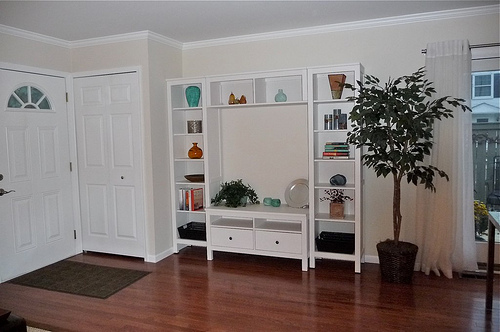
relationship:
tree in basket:
[335, 67, 473, 238] [377, 238, 419, 283]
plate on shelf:
[286, 178, 312, 209] [211, 202, 309, 216]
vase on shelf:
[184, 86, 202, 107] [176, 107, 208, 112]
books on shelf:
[322, 140, 352, 158] [313, 157, 361, 164]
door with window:
[1, 62, 82, 288] [8, 84, 57, 111]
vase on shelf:
[186, 142, 203, 158] [177, 157, 205, 162]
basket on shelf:
[315, 231, 355, 255] [313, 251, 356, 263]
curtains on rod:
[409, 41, 478, 279] [422, 42, 500, 55]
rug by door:
[7, 259, 153, 300] [1, 62, 82, 288]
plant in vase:
[318, 188, 353, 203] [329, 201, 346, 218]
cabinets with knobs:
[209, 222, 304, 256] [228, 237, 280, 245]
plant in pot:
[211, 178, 260, 206] [240, 195, 247, 205]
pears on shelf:
[228, 93, 249, 105] [209, 102, 258, 107]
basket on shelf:
[178, 221, 207, 242] [178, 238, 206, 249]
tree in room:
[335, 67, 473, 238] [1, 1, 498, 331]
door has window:
[1, 62, 82, 288] [8, 84, 57, 111]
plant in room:
[318, 188, 353, 203] [1, 1, 498, 331]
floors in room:
[2, 244, 498, 331] [1, 1, 498, 331]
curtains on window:
[409, 41, 478, 279] [471, 70, 499, 242]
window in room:
[471, 70, 499, 242] [1, 1, 498, 331]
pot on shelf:
[328, 73, 347, 98] [314, 98, 355, 105]